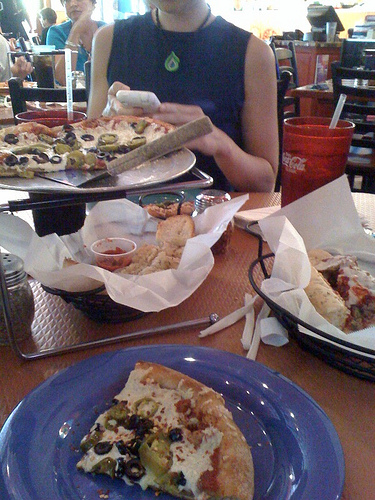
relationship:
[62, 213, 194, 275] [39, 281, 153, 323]
bread in basket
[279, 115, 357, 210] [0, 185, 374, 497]
cup in table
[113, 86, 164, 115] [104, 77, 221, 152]
cell phone in hands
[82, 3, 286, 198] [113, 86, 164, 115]
girl holding cell phone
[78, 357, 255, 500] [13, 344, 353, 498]
pizza on plate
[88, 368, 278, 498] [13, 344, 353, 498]
pizza on plate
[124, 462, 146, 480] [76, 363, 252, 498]
olives are on pizza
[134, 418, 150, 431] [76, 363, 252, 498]
olives are on pizza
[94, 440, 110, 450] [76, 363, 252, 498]
olives are on pizza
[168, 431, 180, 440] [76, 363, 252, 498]
olives are on pizza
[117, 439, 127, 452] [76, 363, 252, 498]
olives are on pizza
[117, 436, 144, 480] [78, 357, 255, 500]
black olives are on pizza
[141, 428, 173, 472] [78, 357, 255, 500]
jalapenos are on pizza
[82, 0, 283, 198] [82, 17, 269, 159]
girl wearing top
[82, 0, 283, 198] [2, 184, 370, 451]
girl sitting at table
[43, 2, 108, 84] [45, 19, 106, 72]
woman wearing shirt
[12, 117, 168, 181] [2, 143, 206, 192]
pizza on serving tray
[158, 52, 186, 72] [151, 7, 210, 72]
pendant on necklace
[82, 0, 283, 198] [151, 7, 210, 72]
girl wearing necklace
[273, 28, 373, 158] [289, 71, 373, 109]
chairs are at table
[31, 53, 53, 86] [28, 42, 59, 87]
soft drink in cup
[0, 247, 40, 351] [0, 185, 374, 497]
pepper shaker on table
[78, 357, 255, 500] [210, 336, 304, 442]
pizza on plate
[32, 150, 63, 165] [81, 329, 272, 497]
olives on pizza